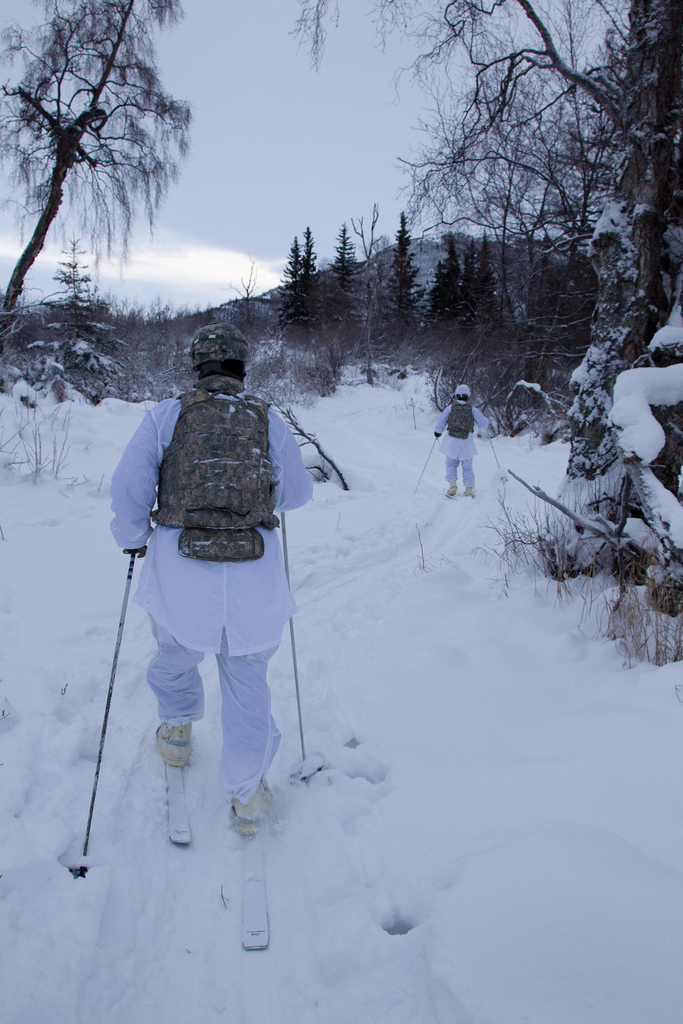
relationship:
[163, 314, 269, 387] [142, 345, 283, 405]
hat on head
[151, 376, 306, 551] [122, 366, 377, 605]
backpack on back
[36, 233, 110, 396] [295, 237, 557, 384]
tree in forest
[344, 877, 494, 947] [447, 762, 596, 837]
print in snow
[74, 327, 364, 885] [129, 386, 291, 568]
man wearing backpack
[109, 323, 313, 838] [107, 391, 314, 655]
man wearing jacket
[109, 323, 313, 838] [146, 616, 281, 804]
man wearing pants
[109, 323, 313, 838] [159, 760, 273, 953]
man wearing skis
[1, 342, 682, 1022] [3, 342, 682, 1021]
snow on ground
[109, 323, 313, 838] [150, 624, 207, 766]
man has leg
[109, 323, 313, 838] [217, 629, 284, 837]
man has leg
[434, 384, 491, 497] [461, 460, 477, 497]
man has leg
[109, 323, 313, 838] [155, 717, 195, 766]
man has foot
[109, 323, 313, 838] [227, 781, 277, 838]
man has foot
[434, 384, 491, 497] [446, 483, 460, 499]
man has foot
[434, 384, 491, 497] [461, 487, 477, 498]
man has foot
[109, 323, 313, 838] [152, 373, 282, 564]
man wearing backpack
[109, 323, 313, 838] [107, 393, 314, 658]
man wearing coat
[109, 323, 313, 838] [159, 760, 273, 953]
man on skis